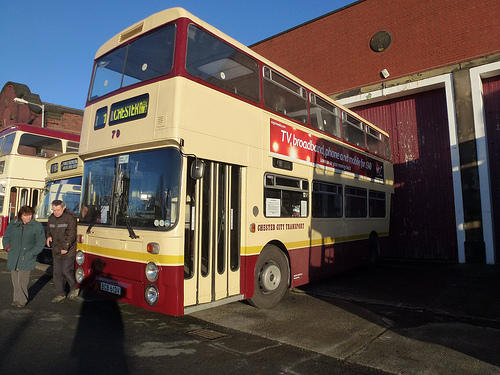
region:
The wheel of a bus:
[250, 251, 293, 306]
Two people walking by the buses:
[2, 201, 82, 300]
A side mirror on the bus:
[192, 157, 207, 178]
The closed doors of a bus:
[185, 163, 250, 298]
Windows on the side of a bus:
[260, 169, 391, 229]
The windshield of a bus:
[82, 152, 179, 230]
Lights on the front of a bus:
[72, 250, 164, 304]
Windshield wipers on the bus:
[85, 195, 137, 240]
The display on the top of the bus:
[92, 98, 149, 127]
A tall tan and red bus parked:
[87, 22, 390, 303]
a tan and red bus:
[75, 7, 394, 319]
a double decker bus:
[70, 9, 396, 315]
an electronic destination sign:
[105, 96, 145, 121]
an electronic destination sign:
[95, 107, 105, 127]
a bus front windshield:
[81, 150, 178, 229]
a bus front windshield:
[36, 176, 81, 216]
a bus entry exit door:
[182, 157, 239, 308]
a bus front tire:
[253, 244, 290, 308]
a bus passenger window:
[184, 21, 260, 103]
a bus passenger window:
[261, 63, 307, 123]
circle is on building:
[363, 26, 397, 57]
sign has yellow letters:
[87, 91, 153, 131]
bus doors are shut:
[178, 156, 250, 308]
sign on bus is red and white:
[267, 116, 388, 184]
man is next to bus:
[43, 194, 84, 306]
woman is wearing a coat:
[1, 201, 49, 311]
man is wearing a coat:
[46, 199, 82, 306]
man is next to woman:
[43, 198, 80, 302]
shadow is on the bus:
[73, 253, 133, 372]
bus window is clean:
[77, 140, 185, 229]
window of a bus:
[70, 145, 137, 240]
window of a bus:
[127, 136, 192, 227]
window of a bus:
[70, 38, 142, 112]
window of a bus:
[106, 13, 187, 97]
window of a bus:
[167, 22, 232, 80]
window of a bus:
[232, 51, 277, 92]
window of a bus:
[259, 169, 316, 224]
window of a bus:
[249, 69, 329, 114]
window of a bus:
[302, 91, 352, 135]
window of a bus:
[292, 169, 364, 227]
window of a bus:
[119, 148, 193, 239]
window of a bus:
[86, 42, 134, 100]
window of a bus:
[122, 6, 189, 98]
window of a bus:
[170, 36, 231, 80]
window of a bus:
[213, 43, 274, 98]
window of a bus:
[256, 162, 314, 222]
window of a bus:
[250, 62, 322, 124]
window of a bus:
[290, 95, 358, 143]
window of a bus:
[337, 111, 379, 152]